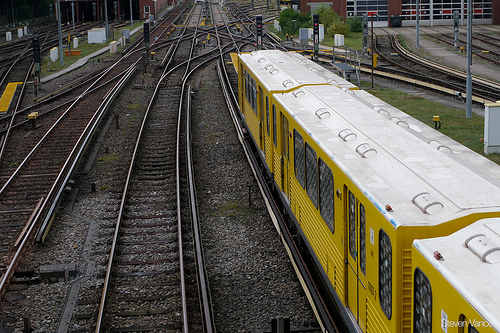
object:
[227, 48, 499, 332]
train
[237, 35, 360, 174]
car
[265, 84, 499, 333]
car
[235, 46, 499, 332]
roof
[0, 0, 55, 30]
rails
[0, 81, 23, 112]
paint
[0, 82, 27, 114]
walkway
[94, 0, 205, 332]
railroad tracks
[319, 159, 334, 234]
paint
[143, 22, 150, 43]
junction box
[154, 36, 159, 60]
switch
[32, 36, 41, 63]
junction box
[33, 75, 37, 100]
switch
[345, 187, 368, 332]
doors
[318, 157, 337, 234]
window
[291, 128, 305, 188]
window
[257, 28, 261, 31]
lights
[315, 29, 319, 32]
lights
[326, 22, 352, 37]
bush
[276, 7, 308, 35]
bush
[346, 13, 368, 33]
bush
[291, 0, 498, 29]
building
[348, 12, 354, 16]
window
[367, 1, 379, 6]
window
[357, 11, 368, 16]
window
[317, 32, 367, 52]
grass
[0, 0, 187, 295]
gravel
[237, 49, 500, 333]
top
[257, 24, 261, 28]
light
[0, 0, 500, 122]
distance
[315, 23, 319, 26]
light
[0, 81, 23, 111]
strip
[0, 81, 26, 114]
cement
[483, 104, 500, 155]
box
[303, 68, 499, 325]
corner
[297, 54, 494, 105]
slat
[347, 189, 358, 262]
windows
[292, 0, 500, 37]
train station